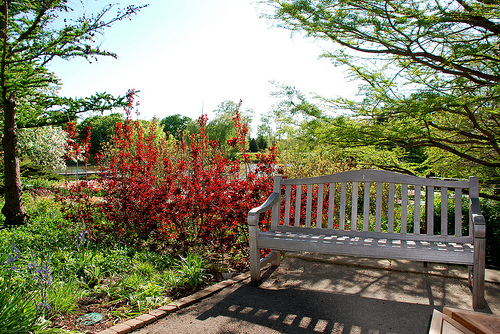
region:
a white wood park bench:
[244, 166, 487, 301]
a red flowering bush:
[62, 89, 334, 246]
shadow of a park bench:
[195, 277, 444, 333]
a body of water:
[46, 165, 304, 179]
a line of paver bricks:
[97, 250, 282, 332]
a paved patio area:
[137, 255, 499, 332]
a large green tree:
[4, 0, 139, 222]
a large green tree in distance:
[80, 112, 123, 161]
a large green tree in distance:
[162, 112, 189, 133]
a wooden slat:
[282, 185, 292, 221]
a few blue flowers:
[4, 230, 57, 313]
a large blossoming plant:
[50, 93, 306, 245]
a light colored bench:
[243, 165, 494, 305]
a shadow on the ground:
[203, 280, 449, 332]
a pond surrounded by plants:
[26, 127, 335, 209]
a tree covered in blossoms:
[11, 120, 96, 177]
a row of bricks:
[96, 271, 236, 332]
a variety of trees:
[63, 103, 272, 163]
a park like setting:
[5, 10, 485, 319]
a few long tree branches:
[286, 9, 487, 192]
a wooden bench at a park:
[234, 169, 494, 323]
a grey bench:
[241, 165, 494, 304]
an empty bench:
[252, 167, 499, 310]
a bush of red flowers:
[63, 85, 273, 290]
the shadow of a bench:
[218, 274, 478, 326]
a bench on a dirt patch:
[241, 163, 498, 310]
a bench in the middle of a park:
[239, 136, 494, 325]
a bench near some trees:
[240, 163, 495, 308]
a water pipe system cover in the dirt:
[71, 306, 115, 328]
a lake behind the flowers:
[64, 145, 339, 190]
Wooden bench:
[245, 175, 486, 305]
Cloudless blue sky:
[36, 0, 413, 115]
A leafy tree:
[0, 0, 122, 211]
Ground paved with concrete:
[100, 260, 495, 330]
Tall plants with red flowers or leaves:
[66, 101, 331, 251]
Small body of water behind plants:
[15, 160, 296, 180]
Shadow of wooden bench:
[210, 260, 440, 330]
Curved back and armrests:
[245, 164, 487, 236]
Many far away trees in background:
[70, 115, 270, 160]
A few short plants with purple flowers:
[0, 245, 50, 326]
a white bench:
[244, 169, 494, 307]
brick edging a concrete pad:
[104, 263, 258, 332]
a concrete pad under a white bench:
[110, 255, 498, 330]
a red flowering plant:
[61, 112, 315, 249]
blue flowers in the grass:
[6, 240, 52, 317]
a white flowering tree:
[19, 125, 71, 174]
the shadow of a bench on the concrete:
[198, 255, 439, 332]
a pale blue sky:
[12, 2, 498, 132]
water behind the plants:
[64, 160, 292, 182]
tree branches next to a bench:
[288, 2, 498, 204]